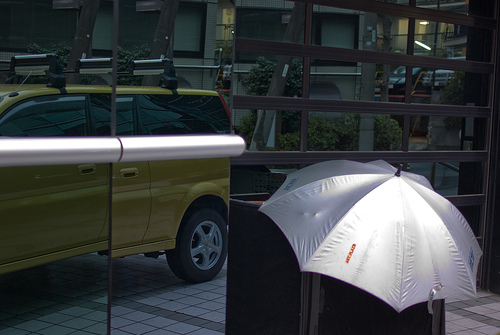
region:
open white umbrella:
[255, 130, 490, 322]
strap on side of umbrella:
[421, 282, 456, 319]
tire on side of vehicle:
[166, 200, 231, 286]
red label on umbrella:
[338, 236, 360, 271]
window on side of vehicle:
[8, 96, 223, 143]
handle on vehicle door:
[116, 163, 148, 185]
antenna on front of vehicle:
[5, 50, 46, 103]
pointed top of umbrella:
[393, 158, 405, 183]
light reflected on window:
[136, 95, 190, 140]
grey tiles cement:
[17, 235, 238, 332]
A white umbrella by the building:
[262, 157, 493, 318]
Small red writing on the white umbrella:
[342, 238, 360, 271]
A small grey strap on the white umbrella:
[424, 281, 442, 321]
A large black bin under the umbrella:
[230, 185, 447, 333]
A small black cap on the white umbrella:
[390, 160, 410, 180]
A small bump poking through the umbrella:
[297, 208, 326, 224]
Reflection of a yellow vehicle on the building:
[0, 73, 245, 278]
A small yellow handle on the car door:
[117, 163, 144, 185]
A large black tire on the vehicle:
[172, 212, 229, 285]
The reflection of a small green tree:
[238, 48, 317, 130]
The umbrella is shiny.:
[253, 130, 493, 330]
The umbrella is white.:
[251, 151, 492, 333]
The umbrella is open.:
[249, 150, 485, 333]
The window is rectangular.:
[226, 96, 306, 161]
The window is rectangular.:
[228, 37, 306, 103]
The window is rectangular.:
[303, 48, 414, 110]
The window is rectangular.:
[304, 101, 408, 159]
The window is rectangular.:
[408, 58, 495, 113]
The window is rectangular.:
[402, 103, 494, 155]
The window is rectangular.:
[308, 1, 412, 60]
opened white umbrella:
[256, 157, 482, 310]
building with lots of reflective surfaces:
[8, 0, 493, 328]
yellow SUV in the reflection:
[5, 81, 235, 269]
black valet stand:
[233, 190, 438, 327]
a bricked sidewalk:
[436, 290, 497, 333]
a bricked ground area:
[0, 240, 220, 330]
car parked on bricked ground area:
[0, 76, 220, 327]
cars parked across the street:
[386, 65, 464, 127]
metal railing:
[0, 135, 261, 176]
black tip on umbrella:
[368, 155, 415, 197]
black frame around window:
[273, 21, 490, 186]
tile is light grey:
[433, 297, 480, 334]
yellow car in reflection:
[7, 98, 202, 290]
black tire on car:
[170, 198, 246, 304]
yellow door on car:
[9, 99, 109, 263]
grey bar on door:
[3, 111, 226, 198]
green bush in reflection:
[296, 102, 405, 156]